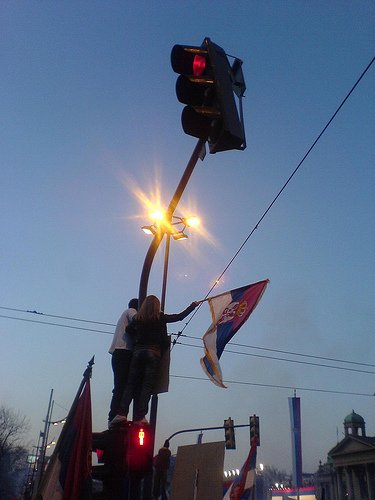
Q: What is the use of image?
A: Check.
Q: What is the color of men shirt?
A: White.